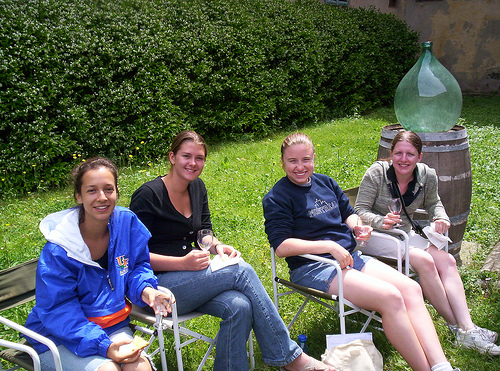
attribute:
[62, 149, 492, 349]
women — four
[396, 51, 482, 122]
bottle — glass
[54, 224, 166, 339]
jacket — blue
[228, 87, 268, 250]
flowers — yellow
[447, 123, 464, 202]
barrel — wooden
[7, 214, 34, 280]
grass — tall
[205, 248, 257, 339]
jeans — blue denim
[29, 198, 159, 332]
jacket — blue 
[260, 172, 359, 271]
sweater — blue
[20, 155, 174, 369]
woman — sitting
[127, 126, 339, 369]
woman — sitting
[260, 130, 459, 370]
woman — sitting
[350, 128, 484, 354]
woman — sitting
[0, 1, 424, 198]
plant — big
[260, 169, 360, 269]
shirt — blue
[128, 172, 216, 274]
shirt — black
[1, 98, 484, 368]
grass — green